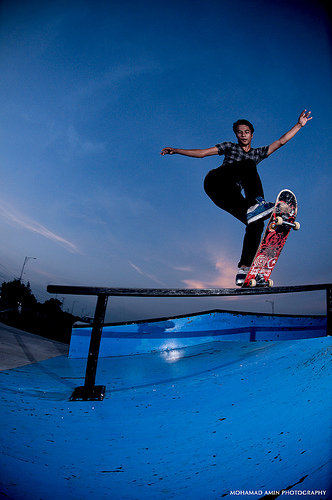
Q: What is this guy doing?
A: Skateboarding.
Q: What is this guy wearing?
A: T-shirt and pants.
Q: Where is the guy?
A: Standing on the black skateboard railing.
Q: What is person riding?
A: Skateboard.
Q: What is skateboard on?
A: Railing.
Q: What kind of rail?
A: Metal.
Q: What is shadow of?
A: Rail.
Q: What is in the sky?
A: Clouds.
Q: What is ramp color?
A: Blue.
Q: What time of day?
A: Sunset.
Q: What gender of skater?
A: Male.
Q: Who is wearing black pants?
A: Skater.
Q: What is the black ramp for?
A: Skating.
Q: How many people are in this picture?
A: One.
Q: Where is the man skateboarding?
A: On the railing.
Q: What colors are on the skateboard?
A: Red, white and black.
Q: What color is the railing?
A: Black.